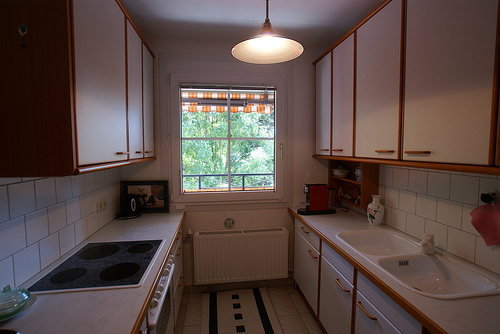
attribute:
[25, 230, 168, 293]
top — stove's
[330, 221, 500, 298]
sink — white, kitchen's, double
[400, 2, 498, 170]
cabinet — white, overhead, wooden, kitchen's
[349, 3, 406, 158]
cabinet — white, overhead, wooden, kitchen's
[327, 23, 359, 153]
cabinet — white, overhead, wooden, kitchen's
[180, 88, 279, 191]
window — kitchen's, large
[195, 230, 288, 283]
unit — airconditioning/heat, air conditioning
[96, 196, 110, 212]
outlet — power, electrical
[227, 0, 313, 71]
light — hanging, fixture, kitchen's, bright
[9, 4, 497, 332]
kitchen — here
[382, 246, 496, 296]
sink — white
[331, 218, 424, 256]
sink — white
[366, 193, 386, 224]
dish — glass, white, green, candy, small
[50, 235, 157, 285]
burners — here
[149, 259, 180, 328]
handle — white, wooden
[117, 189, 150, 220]
kettle — black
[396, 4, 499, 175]
frame — wood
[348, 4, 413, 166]
frame — wood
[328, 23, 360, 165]
frame — wood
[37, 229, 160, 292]
stovetop — glass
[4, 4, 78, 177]
end — cabinet's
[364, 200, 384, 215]
flower — pink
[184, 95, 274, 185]
view — trees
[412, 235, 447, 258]
faucet — white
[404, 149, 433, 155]
cabinet handle — wooden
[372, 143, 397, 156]
cabinet handle — wooden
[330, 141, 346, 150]
cabinet handle — wooden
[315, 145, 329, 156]
cabinet handle — wooden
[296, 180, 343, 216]
appliance — red, black, sitting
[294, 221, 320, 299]
cabinet — kitchen's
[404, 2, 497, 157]
door — white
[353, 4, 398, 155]
door — white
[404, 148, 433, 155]
handle — wooden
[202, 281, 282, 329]
rug — small, dotted, black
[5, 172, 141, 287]
backsplash — white, tiled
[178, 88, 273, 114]
over hang — white, orange